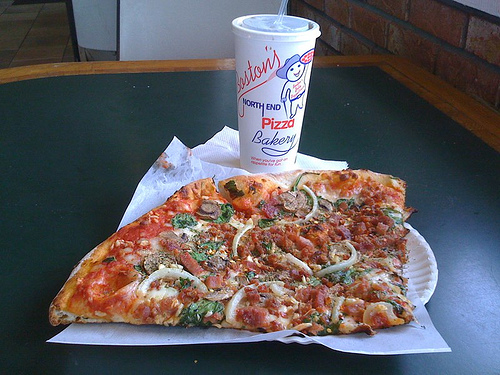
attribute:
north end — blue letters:
[239, 97, 280, 119]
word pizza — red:
[259, 118, 296, 131]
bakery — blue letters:
[253, 130, 298, 157]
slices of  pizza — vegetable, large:
[49, 169, 416, 337]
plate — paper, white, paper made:
[125, 171, 441, 344]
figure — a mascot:
[276, 53, 306, 118]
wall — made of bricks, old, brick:
[290, 0, 499, 109]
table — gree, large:
[1, 66, 498, 373]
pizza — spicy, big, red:
[47, 177, 370, 335]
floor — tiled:
[1, 0, 78, 68]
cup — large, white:
[231, 2, 321, 171]